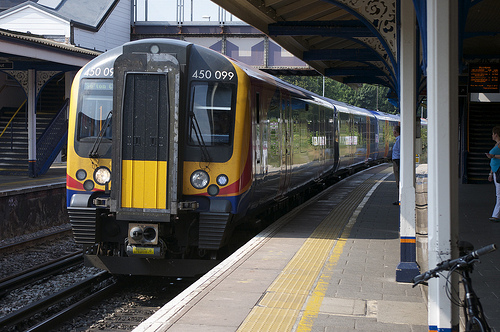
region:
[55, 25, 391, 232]
the train is yellow.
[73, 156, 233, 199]
One light is on.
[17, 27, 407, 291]
One train on a track.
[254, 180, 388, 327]
Yellow stripes on the ground.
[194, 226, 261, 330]
The concrete is grey.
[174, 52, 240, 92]
the train says 450 099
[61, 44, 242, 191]
The window is transparent.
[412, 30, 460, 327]
The pole is white.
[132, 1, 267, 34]
The sky is blue.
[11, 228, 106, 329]
Gravel in between the tracks.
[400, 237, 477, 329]
Handlebars of a bike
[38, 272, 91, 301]
Gravel around train tracks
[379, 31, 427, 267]
Support posts at a train station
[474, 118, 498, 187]
A woman in a blue shirt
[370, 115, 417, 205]
A man waiting at a train station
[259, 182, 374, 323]
Yellow paint on a train platform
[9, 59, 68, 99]
Decorative white latticework with blue trim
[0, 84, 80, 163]
A stairway at a train station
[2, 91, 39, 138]
A yellow center rail on a staircase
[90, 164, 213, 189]
Headlights on the front of a train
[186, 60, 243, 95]
Numbers on train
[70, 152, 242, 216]
2 Large circle lights on front of train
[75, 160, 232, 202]
4 small circle lights on front of train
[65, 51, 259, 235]
Majority color of train is yellow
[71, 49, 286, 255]
3 colors that make up the train is yellow, red and blue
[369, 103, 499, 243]
2 people standing on train station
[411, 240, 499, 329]
Black bike leaning against post in foreground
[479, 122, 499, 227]
Woman is wearing white pants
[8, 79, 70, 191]
Blue stairs on left side of train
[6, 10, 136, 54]
White building on left side of train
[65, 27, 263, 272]
Back view of a train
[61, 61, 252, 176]
Back of the train has two windows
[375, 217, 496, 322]
A bicycle is in the foreground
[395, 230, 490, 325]
The bicycle is all black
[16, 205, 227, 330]
Train is on the train tracks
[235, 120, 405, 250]
Train is casting a shadow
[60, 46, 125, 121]
Sunlight is reflecting off the top of train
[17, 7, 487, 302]
Photo was taken in the daytime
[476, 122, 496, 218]
A person is on the right side of the photo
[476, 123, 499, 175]
The person is wearing a teal colored shirt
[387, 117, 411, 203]
a person at the station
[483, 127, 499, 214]
a person at the station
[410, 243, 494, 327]
s bike is parked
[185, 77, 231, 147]
a glass window on a train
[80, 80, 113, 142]
a glass window on a train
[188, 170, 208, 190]
a light on a train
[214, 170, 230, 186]
a light on a train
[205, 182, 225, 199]
a light on a train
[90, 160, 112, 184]
a light on a train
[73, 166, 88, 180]
a light on a train